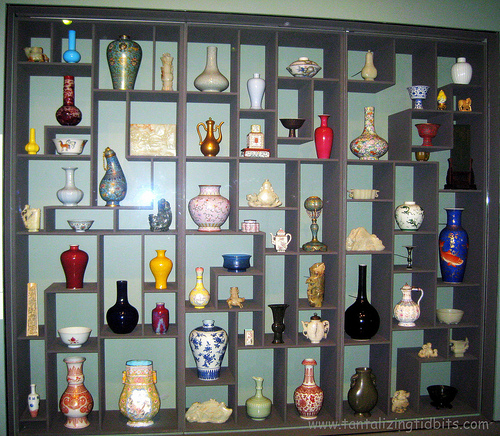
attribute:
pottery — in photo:
[102, 28, 146, 100]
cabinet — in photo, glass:
[2, 3, 498, 435]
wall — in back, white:
[0, 2, 497, 434]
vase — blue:
[59, 26, 84, 65]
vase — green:
[103, 31, 145, 93]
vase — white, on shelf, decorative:
[244, 70, 267, 114]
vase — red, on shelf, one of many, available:
[313, 111, 336, 162]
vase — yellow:
[23, 125, 42, 158]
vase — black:
[103, 278, 139, 335]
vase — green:
[241, 377, 276, 425]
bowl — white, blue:
[64, 218, 98, 232]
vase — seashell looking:
[342, 224, 387, 256]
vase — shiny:
[145, 244, 177, 294]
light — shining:
[126, 181, 162, 215]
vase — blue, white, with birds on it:
[187, 317, 230, 385]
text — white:
[301, 413, 491, 436]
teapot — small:
[195, 114, 227, 158]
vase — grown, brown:
[300, 255, 329, 309]